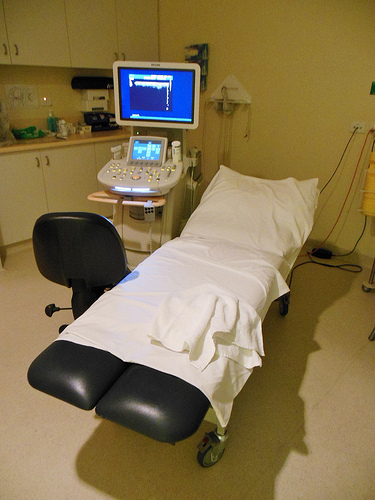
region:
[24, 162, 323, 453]
a hospital examination bed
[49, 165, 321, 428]
the bed is covered in a white sheet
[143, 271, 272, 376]
a white towel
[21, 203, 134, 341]
a black office chair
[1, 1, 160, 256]
top and bottom cupboards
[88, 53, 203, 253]
medical equipment is lit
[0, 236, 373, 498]
the floor is tiled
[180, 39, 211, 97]
three boxes of gloves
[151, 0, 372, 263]
the wall is painted yellow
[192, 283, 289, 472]
two visible black wheels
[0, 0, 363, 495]
a room in which it appears that medical exams are performed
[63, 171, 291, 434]
bed for patient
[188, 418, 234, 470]
wheel attached to bed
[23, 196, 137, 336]
rolling chair beside bed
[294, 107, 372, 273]
cords hanging from wall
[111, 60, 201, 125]
large monitor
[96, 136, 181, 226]
a medical device's dials and controls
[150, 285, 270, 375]
white towel on bed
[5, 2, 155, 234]
white cabinets lining wall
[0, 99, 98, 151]
various objects on counter-top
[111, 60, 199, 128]
a computer monitor in the office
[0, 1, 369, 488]
a doctors office with a table and computer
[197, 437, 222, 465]
a wheel on the patient's table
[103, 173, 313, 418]
blankets on the patient table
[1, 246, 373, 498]
the floor of the office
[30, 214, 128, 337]
the chair sitting next to the table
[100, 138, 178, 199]
the rest of the computer in the office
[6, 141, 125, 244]
some cabinets on the side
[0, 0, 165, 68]
more cabinets on the side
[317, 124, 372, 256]
some wires hanging on the wall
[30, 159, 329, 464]
medical examination table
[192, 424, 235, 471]
lockable wheel on medical examination table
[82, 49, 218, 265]
medical ultrasound machine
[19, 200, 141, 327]
back view of a rolling office chair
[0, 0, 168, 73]
side by side cabinets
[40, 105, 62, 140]
bottle of green hand sanitizer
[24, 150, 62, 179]
cabinet handles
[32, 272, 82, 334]
adjustment knob on an office chair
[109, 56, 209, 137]
viewing screen on an ultrasound machine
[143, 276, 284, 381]
white towel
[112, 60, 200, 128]
blue computer screen powered on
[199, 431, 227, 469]
left wheel of a rolling doctor's chair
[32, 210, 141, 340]
back of cushioned office chair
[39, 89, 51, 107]
electronic device with on light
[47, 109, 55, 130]
hand sanitizer in a pump bottle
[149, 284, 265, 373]
white towel on a white cloth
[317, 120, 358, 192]
chord going into a wall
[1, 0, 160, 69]
cabinet with silver handles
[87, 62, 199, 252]
hospital workstation with screen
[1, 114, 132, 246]
cabinet drawers with silver handles